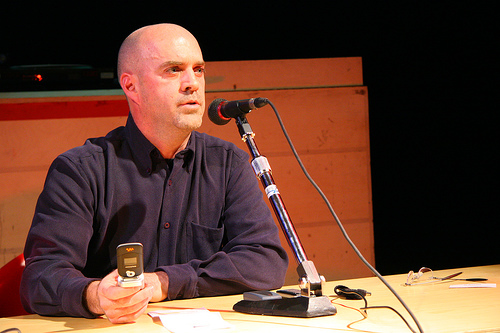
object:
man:
[20, 22, 289, 325]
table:
[1, 267, 500, 333]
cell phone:
[116, 242, 144, 289]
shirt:
[19, 112, 289, 319]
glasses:
[400, 266, 489, 287]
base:
[232, 291, 337, 319]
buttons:
[163, 222, 171, 230]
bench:
[0, 56, 375, 277]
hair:
[115, 27, 148, 73]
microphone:
[207, 96, 270, 126]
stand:
[204, 98, 337, 318]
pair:
[402, 266, 489, 286]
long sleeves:
[19, 150, 93, 320]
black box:
[0, 62, 117, 93]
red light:
[34, 74, 44, 81]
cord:
[267, 101, 424, 333]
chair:
[0, 252, 28, 320]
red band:
[217, 101, 232, 121]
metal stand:
[226, 114, 340, 319]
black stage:
[0, 0, 498, 277]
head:
[116, 23, 206, 131]